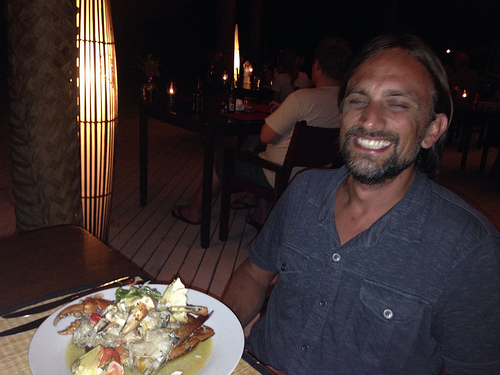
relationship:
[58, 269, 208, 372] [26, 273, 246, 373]
foods on plate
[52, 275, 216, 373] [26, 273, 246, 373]
foods on plate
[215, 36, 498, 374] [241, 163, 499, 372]
man wearing shirt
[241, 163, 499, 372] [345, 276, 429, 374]
shirt has pocket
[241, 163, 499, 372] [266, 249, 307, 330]
shirt has pocket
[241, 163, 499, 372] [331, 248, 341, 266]
shirt has button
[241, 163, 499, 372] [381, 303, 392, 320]
shirt has button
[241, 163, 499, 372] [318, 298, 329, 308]
shirt has button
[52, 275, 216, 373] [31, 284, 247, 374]
foods on plate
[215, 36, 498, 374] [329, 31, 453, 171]
man has hair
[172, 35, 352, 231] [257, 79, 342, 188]
man wearing shirt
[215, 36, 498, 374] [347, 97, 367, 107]
man has eye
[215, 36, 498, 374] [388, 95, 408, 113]
man has eye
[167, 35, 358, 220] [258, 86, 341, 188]
man wearing shirt